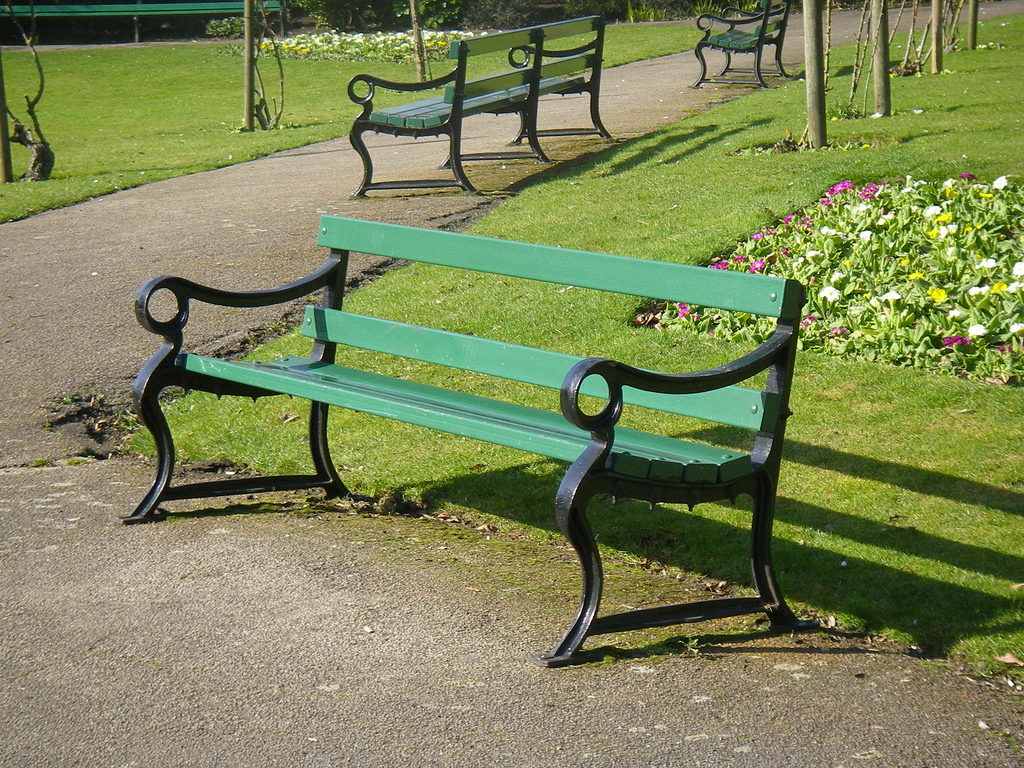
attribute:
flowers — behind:
[939, 335, 971, 351]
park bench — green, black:
[127, 213, 817, 669]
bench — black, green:
[689, 3, 797, 92]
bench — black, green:
[135, 213, 825, 666]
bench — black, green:
[350, 11, 613, 198]